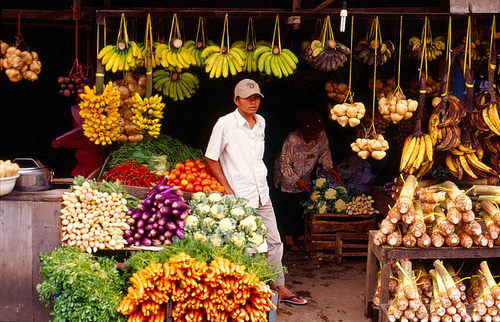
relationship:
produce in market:
[37, 136, 291, 321] [0, 0, 500, 321]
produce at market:
[37, 136, 291, 321] [0, 0, 500, 321]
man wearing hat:
[205, 79, 307, 308] [234, 77, 267, 101]